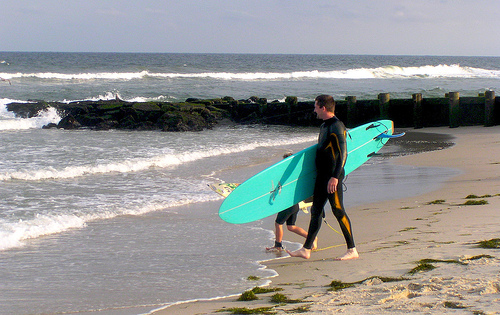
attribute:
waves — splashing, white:
[1, 66, 498, 258]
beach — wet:
[138, 124, 497, 314]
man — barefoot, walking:
[287, 94, 360, 262]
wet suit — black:
[303, 117, 356, 251]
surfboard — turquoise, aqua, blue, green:
[217, 119, 407, 226]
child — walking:
[267, 203, 319, 250]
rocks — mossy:
[59, 100, 237, 133]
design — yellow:
[325, 132, 354, 238]